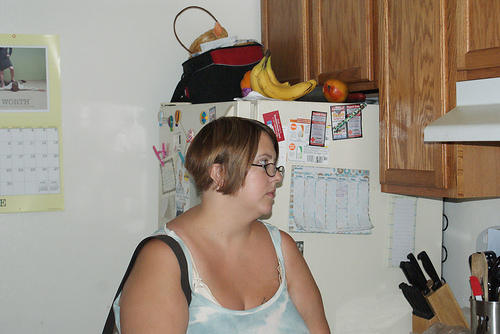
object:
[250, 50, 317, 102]
bananas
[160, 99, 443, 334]
fridge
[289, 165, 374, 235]
calendar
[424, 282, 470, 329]
container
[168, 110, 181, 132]
magnets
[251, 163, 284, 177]
glasses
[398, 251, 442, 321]
knives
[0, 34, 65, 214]
calendar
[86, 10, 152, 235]
wall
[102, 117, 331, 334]
lady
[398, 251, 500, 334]
utensils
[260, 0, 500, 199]
cabinets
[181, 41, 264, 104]
bag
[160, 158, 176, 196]
papers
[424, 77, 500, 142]
fan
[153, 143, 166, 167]
clip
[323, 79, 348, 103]
apple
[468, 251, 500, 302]
spoon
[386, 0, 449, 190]
door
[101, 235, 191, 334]
purse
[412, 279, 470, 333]
holder